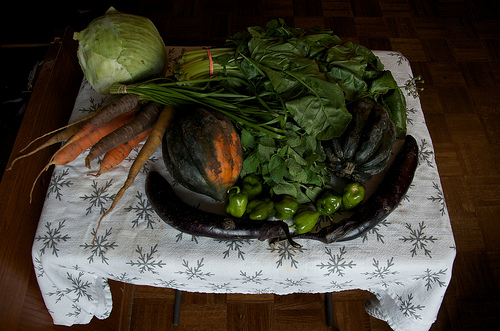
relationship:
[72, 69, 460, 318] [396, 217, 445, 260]
tablecloth has snowflakes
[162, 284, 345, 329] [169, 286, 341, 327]
tray has legs